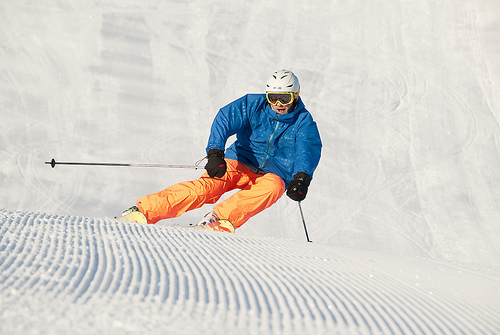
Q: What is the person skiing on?
A: Snow.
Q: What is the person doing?
A: Skiing on a hill.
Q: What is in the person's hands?
A: Ski poles.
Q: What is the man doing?
A: Skiing.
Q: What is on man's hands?
A: Gloves.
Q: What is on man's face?
A: Goggles.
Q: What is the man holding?
A: Ski poles.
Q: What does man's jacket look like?
A: Blue.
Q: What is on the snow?
A: Tracks.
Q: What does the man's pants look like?
A: Orange.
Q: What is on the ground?
A: Snow.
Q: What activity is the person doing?
A: Skiing.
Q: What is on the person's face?
A: Goggles.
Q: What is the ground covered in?
A: Snow.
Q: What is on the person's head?
A: A helmet.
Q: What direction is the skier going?
A: Downward.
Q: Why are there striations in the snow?
A: From people skiing.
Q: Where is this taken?
A: On a ski slope.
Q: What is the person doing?
A: Skiing.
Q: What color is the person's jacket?
A: Blue.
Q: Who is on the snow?
A: A man.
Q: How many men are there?
A: One.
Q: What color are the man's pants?
A: Orange.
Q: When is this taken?
A: During the day.